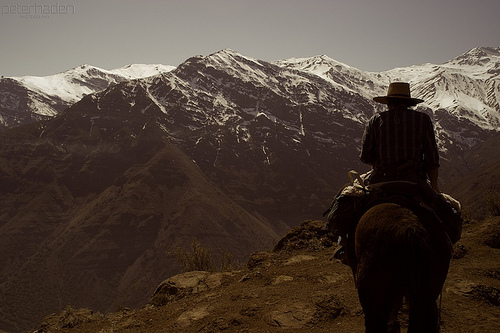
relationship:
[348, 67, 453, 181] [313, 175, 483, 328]
man on horse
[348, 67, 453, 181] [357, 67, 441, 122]
man has head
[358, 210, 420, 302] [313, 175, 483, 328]
end of horse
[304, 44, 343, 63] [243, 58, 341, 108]
snow on mountain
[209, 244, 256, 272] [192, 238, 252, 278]
rock on side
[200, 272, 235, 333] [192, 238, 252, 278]
grass on side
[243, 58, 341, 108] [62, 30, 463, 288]
mountain in background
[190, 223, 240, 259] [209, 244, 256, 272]
brush by rock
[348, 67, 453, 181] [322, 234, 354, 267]
man has foot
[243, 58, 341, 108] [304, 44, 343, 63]
mountain with snow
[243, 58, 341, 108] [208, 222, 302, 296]
mountain near cliff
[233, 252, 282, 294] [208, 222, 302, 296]
edge of cliff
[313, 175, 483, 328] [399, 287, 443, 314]
horse has parts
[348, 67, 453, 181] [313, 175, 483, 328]
cowboy on horse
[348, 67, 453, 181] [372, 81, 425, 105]
man in cap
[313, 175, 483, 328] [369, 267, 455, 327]
horse has tail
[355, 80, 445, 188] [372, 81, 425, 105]
man has cap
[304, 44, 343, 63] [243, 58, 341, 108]
snow covered mountain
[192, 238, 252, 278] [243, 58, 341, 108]
side of mountain